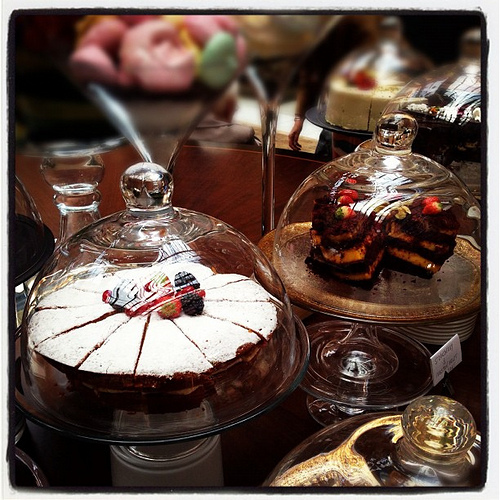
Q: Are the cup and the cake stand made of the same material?
A: Yes, both the cup and the cake stand are made of glass.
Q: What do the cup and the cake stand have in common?
A: The material, both the cup and the cake stand are glass.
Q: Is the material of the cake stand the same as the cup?
A: Yes, both the cake stand and the cup are made of glass.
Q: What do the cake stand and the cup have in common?
A: The material, both the cake stand and the cup are glass.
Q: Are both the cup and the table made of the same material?
A: No, the cup is made of glass and the table is made of wood.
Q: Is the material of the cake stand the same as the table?
A: No, the cake stand is made of glass and the table is made of wood.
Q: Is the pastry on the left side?
A: No, the pastry is on the right of the image.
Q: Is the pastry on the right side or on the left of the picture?
A: The pastry is on the right of the image.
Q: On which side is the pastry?
A: The pastry is on the right of the image.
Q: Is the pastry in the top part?
A: Yes, the pastry is in the top of the image.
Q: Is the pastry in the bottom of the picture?
A: No, the pastry is in the top of the image.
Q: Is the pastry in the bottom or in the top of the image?
A: The pastry is in the top of the image.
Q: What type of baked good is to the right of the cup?
A: The food is a pastry.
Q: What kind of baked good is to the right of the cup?
A: The food is a pastry.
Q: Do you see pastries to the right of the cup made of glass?
A: Yes, there is a pastry to the right of the cup.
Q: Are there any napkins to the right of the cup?
A: No, there is a pastry to the right of the cup.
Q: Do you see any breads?
A: No, there are no breads.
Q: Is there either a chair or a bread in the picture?
A: No, there are no breads or chairs.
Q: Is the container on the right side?
A: Yes, the container is on the right of the image.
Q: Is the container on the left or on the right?
A: The container is on the right of the image.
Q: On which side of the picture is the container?
A: The container is on the right of the image.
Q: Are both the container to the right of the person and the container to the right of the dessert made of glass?
A: Yes, both the container and the container are made of glass.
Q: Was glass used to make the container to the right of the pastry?
A: Yes, the container is made of glass.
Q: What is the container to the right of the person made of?
A: The container is made of glass.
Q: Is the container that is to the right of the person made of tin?
A: No, the container is made of glass.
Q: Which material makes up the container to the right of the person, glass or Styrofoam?
A: The container is made of glass.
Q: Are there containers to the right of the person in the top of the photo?
A: Yes, there is a container to the right of the person.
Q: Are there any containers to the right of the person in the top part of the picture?
A: Yes, there is a container to the right of the person.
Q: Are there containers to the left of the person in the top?
A: No, the container is to the right of the person.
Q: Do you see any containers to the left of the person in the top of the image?
A: No, the container is to the right of the person.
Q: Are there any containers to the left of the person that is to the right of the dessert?
A: No, the container is to the right of the person.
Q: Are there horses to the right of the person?
A: No, there is a container to the right of the person.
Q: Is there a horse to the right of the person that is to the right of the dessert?
A: No, there is a container to the right of the person.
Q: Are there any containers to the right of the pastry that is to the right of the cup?
A: Yes, there is a container to the right of the pastry.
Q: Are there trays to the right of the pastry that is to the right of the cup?
A: No, there is a container to the right of the pastry.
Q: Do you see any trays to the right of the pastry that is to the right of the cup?
A: No, there is a container to the right of the pastry.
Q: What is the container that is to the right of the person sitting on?
A: The container is sitting on the table.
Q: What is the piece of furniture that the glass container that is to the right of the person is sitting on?
A: The piece of furniture is a table.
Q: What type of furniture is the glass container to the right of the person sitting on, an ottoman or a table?
A: The container is sitting on a table.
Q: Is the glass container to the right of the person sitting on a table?
A: Yes, the container is sitting on a table.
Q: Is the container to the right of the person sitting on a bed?
A: No, the container is sitting on a table.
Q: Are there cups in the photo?
A: Yes, there is a cup.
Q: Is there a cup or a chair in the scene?
A: Yes, there is a cup.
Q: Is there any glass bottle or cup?
A: Yes, there is a glass cup.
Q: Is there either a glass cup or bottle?
A: Yes, there is a glass cup.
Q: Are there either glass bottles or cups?
A: Yes, there is a glass cup.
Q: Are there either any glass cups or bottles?
A: Yes, there is a glass cup.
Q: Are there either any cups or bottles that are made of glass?
A: Yes, the cup is made of glass.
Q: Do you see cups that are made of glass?
A: Yes, there is a cup that is made of glass.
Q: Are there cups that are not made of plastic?
A: Yes, there is a cup that is made of glass.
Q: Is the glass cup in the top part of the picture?
A: Yes, the cup is in the top of the image.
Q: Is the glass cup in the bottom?
A: No, the cup is in the top of the image.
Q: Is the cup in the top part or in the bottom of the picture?
A: The cup is in the top of the image.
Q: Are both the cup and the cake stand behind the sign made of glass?
A: Yes, both the cup and the cake stand are made of glass.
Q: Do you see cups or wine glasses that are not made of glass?
A: No, there is a cup but it is made of glass.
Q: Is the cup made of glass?
A: Yes, the cup is made of glass.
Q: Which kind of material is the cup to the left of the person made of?
A: The cup is made of glass.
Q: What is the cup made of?
A: The cup is made of glass.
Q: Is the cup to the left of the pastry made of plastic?
A: No, the cup is made of glass.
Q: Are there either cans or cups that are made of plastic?
A: No, there is a cup but it is made of glass.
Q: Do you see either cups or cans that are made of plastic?
A: No, there is a cup but it is made of glass.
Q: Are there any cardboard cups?
A: No, there is a cup but it is made of glass.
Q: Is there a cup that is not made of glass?
A: No, there is a cup but it is made of glass.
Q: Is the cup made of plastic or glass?
A: The cup is made of glass.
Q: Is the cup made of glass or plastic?
A: The cup is made of glass.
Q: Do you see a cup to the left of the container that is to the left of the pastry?
A: Yes, there is a cup to the left of the container.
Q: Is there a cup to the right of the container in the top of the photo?
A: No, the cup is to the left of the container.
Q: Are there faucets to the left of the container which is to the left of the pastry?
A: No, there is a cup to the left of the container.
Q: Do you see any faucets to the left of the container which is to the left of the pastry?
A: No, there is a cup to the left of the container.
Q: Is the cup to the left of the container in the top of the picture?
A: Yes, the cup is to the left of the container.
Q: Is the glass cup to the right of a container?
A: No, the cup is to the left of a container.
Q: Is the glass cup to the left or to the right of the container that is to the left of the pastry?
A: The cup is to the left of the container.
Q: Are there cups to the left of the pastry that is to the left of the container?
A: Yes, there is a cup to the left of the pastry.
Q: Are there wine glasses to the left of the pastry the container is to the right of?
A: No, there is a cup to the left of the pastry.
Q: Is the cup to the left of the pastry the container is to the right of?
A: Yes, the cup is to the left of the pastry.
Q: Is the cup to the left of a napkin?
A: No, the cup is to the left of the pastry.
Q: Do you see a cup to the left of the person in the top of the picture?
A: Yes, there is a cup to the left of the person.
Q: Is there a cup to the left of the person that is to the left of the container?
A: Yes, there is a cup to the left of the person.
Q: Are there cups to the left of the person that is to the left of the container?
A: Yes, there is a cup to the left of the person.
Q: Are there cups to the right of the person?
A: No, the cup is to the left of the person.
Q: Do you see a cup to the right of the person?
A: No, the cup is to the left of the person.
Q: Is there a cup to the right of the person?
A: No, the cup is to the left of the person.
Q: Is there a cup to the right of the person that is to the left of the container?
A: No, the cup is to the left of the person.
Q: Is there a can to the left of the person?
A: No, there is a cup to the left of the person.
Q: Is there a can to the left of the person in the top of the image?
A: No, there is a cup to the left of the person.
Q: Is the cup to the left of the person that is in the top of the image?
A: Yes, the cup is to the left of the person.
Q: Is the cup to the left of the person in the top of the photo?
A: Yes, the cup is to the left of the person.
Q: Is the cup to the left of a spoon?
A: No, the cup is to the left of the person.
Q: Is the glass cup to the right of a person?
A: No, the cup is to the left of a person.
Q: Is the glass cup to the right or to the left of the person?
A: The cup is to the left of the person.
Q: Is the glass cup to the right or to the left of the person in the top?
A: The cup is to the left of the person.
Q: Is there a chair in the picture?
A: No, there are no chairs.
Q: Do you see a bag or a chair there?
A: No, there are no chairs or bags.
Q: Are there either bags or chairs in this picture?
A: No, there are no chairs or bags.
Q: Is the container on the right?
A: Yes, the container is on the right of the image.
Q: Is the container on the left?
A: No, the container is on the right of the image.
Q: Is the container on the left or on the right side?
A: The container is on the right of the image.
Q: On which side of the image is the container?
A: The container is on the right of the image.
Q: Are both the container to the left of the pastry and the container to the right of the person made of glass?
A: Yes, both the container and the container are made of glass.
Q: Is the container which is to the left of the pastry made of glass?
A: Yes, the container is made of glass.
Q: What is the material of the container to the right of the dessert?
A: The container is made of glass.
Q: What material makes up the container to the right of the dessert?
A: The container is made of glass.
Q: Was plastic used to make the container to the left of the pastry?
A: No, the container is made of glass.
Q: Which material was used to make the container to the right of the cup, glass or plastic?
A: The container is made of glass.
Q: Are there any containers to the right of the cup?
A: Yes, there is a container to the right of the cup.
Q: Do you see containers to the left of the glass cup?
A: No, the container is to the right of the cup.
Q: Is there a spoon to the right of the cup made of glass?
A: No, there is a container to the right of the cup.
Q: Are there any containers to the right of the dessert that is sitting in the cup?
A: Yes, there is a container to the right of the dessert.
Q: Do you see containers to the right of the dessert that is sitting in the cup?
A: Yes, there is a container to the right of the dessert.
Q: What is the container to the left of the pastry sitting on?
A: The container is sitting on the table.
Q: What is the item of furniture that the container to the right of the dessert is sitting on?
A: The piece of furniture is a table.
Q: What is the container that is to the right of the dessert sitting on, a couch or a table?
A: The container is sitting on a table.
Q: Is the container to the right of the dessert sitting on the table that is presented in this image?
A: Yes, the container is sitting on the table.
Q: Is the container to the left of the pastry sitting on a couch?
A: No, the container is sitting on the table.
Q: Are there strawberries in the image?
A: Yes, there is a strawberry.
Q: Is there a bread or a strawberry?
A: Yes, there is a strawberry.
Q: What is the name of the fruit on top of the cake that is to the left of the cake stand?
A: The fruit is a strawberry.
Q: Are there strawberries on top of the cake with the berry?
A: Yes, there is a strawberry on top of the cake.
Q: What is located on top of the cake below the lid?
A: The strawberry is on top of the cake.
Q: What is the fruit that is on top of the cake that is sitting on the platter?
A: The fruit is a strawberry.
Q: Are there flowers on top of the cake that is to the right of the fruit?
A: No, there is a strawberry on top of the cake.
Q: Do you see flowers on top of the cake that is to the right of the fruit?
A: No, there is a strawberry on top of the cake.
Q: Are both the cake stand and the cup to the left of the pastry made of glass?
A: Yes, both the cake stand and the cup are made of glass.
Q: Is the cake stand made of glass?
A: Yes, the cake stand is made of glass.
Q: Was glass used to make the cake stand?
A: Yes, the cake stand is made of glass.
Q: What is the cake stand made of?
A: The cake stand is made of glass.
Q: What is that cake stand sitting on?
A: The cake stand is sitting on the table.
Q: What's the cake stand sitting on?
A: The cake stand is sitting on the table.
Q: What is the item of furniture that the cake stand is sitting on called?
A: The piece of furniture is a table.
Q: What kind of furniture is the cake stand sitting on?
A: The cake stand is sitting on the table.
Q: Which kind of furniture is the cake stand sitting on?
A: The cake stand is sitting on the table.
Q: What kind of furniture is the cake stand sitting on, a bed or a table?
A: The cake stand is sitting on a table.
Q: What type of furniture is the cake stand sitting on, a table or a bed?
A: The cake stand is sitting on a table.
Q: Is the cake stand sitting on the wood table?
A: Yes, the cake stand is sitting on the table.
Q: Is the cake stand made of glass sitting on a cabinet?
A: No, the cake stand is sitting on the table.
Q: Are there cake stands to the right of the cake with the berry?
A: Yes, there is a cake stand to the right of the cake.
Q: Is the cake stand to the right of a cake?
A: Yes, the cake stand is to the right of a cake.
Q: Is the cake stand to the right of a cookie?
A: No, the cake stand is to the right of a cake.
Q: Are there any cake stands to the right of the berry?
A: Yes, there is a cake stand to the right of the berry.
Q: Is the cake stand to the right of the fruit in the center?
A: Yes, the cake stand is to the right of the berry.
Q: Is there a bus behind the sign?
A: No, there is a cake stand behind the sign.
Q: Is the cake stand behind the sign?
A: Yes, the cake stand is behind the sign.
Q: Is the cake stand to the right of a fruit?
A: Yes, the cake stand is to the right of a fruit.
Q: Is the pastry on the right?
A: Yes, the pastry is on the right of the image.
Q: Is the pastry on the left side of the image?
A: No, the pastry is on the right of the image.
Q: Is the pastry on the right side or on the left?
A: The pastry is on the right of the image.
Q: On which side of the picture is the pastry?
A: The pastry is on the right of the image.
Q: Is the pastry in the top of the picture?
A: Yes, the pastry is in the top of the image.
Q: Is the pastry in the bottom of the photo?
A: No, the pastry is in the top of the image.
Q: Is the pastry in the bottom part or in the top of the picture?
A: The pastry is in the top of the image.